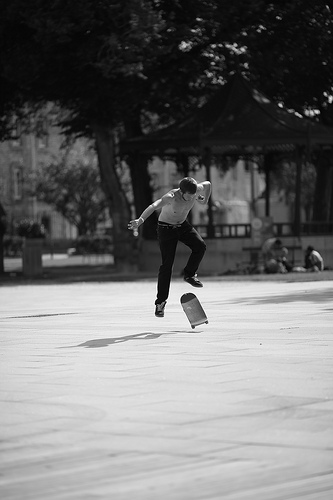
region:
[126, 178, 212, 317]
A man doing a skateboard trick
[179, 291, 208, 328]
A skateboard in the air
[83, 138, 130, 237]
A large tree trunk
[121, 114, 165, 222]
A large tree trunk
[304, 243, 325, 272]
A person sitting down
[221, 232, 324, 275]
A small group of people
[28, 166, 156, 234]
A tree in the distance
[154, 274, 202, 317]
A pair of shoes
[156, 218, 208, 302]
A pair of pants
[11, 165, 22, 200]
A window on a large building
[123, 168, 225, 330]
a guy in the air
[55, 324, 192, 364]
the shadow of a guy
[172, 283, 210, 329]
a skateboard thats black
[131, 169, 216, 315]
a man in black pants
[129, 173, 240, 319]
a man without a shirt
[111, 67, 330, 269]
a big gazebo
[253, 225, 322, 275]
a couple of guys sitting together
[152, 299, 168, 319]
a single skateboarding shoe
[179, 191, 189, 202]
a man's beard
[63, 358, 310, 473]
a piece of pavement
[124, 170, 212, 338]
skater and board above the ground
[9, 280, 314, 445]
wide expanse of paved ground for skateboarder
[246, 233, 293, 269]
person huddled over on bench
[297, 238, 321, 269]
person crouched down on ground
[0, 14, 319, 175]
tall trees and building in background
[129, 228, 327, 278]
low wall at edge of park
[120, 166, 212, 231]
arms and shoulder forming a slant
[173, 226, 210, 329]
knee bent over skateboard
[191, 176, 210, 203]
hand curled under bent arm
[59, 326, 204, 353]
shadow of skater and board on ground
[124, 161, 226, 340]
a guy in the air with his skateboard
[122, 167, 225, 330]
a guy without a shirt playing skateboard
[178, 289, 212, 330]
a skateboard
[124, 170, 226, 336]
a guy wearing pants playing skateboard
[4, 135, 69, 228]
a part of a building in the background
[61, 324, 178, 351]
a shadow of a person playing skateboard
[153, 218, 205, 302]
pants the guy is wearing while playing skateboard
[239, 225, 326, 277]
people in the background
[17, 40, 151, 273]
trees next to the gazebo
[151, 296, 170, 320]
a shoe the guy is wearing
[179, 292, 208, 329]
black skate board in air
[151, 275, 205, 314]
black and white sneakers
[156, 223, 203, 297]
black colored denim jeans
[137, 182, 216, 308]
man wearing no shirt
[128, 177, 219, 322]
man jumping off skateboard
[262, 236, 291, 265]
person sitting on bench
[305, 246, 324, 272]
person sitting on ground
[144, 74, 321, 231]
gazebo next to skate park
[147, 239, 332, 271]
blocks stacked as barrier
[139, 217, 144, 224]
watch on wrist